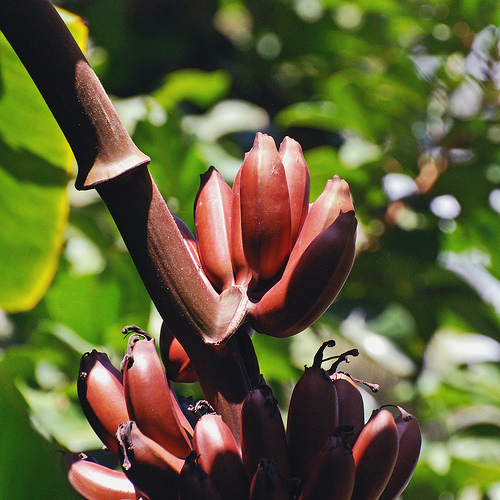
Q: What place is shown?
A: It is a forest.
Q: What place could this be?
A: It is a forest.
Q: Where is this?
A: This is at the forest.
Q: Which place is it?
A: It is a forest.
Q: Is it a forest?
A: Yes, it is a forest.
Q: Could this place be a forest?
A: Yes, it is a forest.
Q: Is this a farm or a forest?
A: It is a forest.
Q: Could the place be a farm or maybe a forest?
A: It is a forest.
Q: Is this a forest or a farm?
A: It is a forest.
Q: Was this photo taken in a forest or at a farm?
A: It was taken at a forest.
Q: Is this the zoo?
A: No, it is the forest.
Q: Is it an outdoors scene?
A: Yes, it is outdoors.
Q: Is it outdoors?
A: Yes, it is outdoors.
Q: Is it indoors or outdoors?
A: It is outdoors.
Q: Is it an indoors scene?
A: No, it is outdoors.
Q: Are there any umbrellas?
A: No, there are no umbrellas.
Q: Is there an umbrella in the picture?
A: No, there are no umbrellas.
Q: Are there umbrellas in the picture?
A: No, there are no umbrellas.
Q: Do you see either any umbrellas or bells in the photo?
A: No, there are no umbrellas or bells.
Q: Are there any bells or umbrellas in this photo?
A: No, there are no umbrellas or bells.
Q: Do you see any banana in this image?
A: Yes, there are bananas.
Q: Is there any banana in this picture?
A: Yes, there are bananas.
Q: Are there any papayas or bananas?
A: Yes, there are bananas.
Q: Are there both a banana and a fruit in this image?
A: Yes, there are both a banana and a fruit.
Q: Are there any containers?
A: No, there are no containers.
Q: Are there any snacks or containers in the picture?
A: No, there are no containers or snacks.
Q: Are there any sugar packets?
A: No, there are no sugar packets.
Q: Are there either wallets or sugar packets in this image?
A: No, there are no sugar packets or wallets.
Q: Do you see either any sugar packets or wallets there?
A: No, there are no sugar packets or wallets.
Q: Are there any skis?
A: No, there are no skis.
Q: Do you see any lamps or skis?
A: No, there are no skis or lamps.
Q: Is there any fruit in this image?
A: Yes, there is a fruit.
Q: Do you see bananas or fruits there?
A: Yes, there is a fruit.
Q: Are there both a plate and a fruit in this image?
A: No, there is a fruit but no plates.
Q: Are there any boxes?
A: No, there are no boxes.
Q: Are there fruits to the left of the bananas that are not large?
A: Yes, there is a fruit to the left of the bananas.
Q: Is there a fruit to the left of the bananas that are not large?
A: Yes, there is a fruit to the left of the bananas.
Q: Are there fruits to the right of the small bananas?
A: No, the fruit is to the left of the bananas.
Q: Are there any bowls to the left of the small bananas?
A: No, there is a fruit to the left of the bananas.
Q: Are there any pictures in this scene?
A: No, there are no pictures.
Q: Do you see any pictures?
A: No, there are no pictures.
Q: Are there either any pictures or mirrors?
A: No, there are no pictures or mirrors.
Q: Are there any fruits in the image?
A: Yes, there is a fruit.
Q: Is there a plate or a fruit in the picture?
A: Yes, there is a fruit.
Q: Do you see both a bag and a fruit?
A: No, there is a fruit but no bags.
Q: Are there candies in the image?
A: No, there are no candies.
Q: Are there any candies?
A: No, there are no candies.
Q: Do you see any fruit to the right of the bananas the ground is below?
A: Yes, there is a fruit to the right of the bananas.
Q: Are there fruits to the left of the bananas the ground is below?
A: No, the fruit is to the right of the bananas.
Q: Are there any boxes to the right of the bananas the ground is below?
A: No, there is a fruit to the right of the bananas.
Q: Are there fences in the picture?
A: No, there are no fences.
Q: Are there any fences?
A: No, there are no fences.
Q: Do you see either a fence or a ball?
A: No, there are no fences or balls.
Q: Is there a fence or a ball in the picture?
A: No, there are no fences or balls.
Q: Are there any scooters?
A: No, there are no scooters.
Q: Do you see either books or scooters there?
A: No, there are no scooters or books.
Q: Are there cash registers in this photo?
A: No, there are no cash registers.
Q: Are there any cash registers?
A: No, there are no cash registers.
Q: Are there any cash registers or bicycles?
A: No, there are no cash registers or bicycles.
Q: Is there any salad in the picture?
A: No, there is no salad.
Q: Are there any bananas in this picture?
A: Yes, there are bananas.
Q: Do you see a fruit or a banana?
A: Yes, there are bananas.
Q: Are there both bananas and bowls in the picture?
A: No, there are bananas but no bowls.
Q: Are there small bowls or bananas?
A: Yes, there are small bananas.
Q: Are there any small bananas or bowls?
A: Yes, there are small bananas.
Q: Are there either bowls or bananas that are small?
A: Yes, the bananas are small.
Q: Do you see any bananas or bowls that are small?
A: Yes, the bananas are small.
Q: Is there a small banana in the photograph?
A: Yes, there are small bananas.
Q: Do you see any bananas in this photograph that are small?
A: Yes, there are bananas that are small.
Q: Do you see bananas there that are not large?
A: Yes, there are small bananas.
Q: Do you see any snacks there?
A: No, there are no snacks.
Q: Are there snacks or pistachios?
A: No, there are no snacks or pistachios.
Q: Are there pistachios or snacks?
A: No, there are no snacks or pistachios.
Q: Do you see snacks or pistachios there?
A: No, there are no snacks or pistachios.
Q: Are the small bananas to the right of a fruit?
A: Yes, the bananas are to the right of a fruit.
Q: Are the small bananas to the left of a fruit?
A: No, the bananas are to the right of a fruit.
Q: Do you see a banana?
A: Yes, there is a banana.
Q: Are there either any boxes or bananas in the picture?
A: Yes, there is a banana.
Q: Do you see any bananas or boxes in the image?
A: Yes, there is a banana.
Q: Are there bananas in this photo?
A: Yes, there is a banana.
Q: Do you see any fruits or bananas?
A: Yes, there is a banana.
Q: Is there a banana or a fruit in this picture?
A: Yes, there is a banana.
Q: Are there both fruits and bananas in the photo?
A: Yes, there are both a banana and a fruit.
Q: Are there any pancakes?
A: No, there are no pancakes.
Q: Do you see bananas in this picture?
A: Yes, there is a banana.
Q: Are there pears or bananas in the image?
A: Yes, there is a banana.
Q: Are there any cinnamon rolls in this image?
A: No, there are no cinnamon rolls.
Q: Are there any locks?
A: No, there are no locks.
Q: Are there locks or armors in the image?
A: No, there are no locks or armors.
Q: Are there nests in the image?
A: No, there are no nests.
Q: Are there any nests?
A: No, there are no nests.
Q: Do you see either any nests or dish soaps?
A: No, there are no nests or dish soaps.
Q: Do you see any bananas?
A: Yes, there is a banana.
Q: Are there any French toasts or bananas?
A: Yes, there is a banana.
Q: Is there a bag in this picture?
A: No, there are no bags.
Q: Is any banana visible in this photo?
A: Yes, there is a banana.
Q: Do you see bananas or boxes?
A: Yes, there is a banana.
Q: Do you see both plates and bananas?
A: No, there is a banana but no plates.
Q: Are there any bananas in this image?
A: Yes, there are bananas.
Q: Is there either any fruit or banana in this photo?
A: Yes, there are bananas.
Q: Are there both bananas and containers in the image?
A: No, there are bananas but no containers.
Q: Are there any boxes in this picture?
A: No, there are no boxes.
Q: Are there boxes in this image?
A: No, there are no boxes.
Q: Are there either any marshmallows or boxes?
A: No, there are no boxes or marshmallows.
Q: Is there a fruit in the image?
A: Yes, there is a fruit.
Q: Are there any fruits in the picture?
A: Yes, there is a fruit.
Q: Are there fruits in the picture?
A: Yes, there is a fruit.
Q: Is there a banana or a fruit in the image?
A: Yes, there is a fruit.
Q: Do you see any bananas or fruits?
A: Yes, there is a fruit.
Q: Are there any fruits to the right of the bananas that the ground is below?
A: Yes, there is a fruit to the right of the bananas.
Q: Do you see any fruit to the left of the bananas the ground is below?
A: No, the fruit is to the right of the bananas.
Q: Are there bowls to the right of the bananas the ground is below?
A: No, there is a fruit to the right of the bananas.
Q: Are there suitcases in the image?
A: No, there are no suitcases.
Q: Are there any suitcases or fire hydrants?
A: No, there are no suitcases or fire hydrants.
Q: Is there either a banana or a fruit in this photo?
A: Yes, there are bananas.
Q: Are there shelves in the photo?
A: No, there are no shelves.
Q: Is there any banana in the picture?
A: Yes, there are bananas.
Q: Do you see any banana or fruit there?
A: Yes, there are bananas.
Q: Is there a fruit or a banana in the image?
A: Yes, there are bananas.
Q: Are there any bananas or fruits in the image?
A: Yes, there are bananas.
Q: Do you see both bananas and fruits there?
A: Yes, there are both bananas and a fruit.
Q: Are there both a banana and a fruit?
A: Yes, there are both a banana and a fruit.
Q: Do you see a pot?
A: No, there are no pots.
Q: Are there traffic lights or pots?
A: No, there are no pots or traffic lights.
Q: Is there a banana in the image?
A: Yes, there is a banana.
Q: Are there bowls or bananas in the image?
A: Yes, there is a banana.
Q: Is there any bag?
A: No, there are no bags.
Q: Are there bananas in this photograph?
A: Yes, there is a banana.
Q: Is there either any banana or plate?
A: Yes, there is a banana.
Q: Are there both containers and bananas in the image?
A: No, there is a banana but no containers.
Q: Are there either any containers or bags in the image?
A: No, there are no containers or bags.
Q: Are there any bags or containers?
A: No, there are no containers or bags.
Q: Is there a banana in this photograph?
A: Yes, there is a banana.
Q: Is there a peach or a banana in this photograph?
A: Yes, there is a banana.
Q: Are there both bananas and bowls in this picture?
A: No, there is a banana but no bowls.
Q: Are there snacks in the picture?
A: No, there are no snacks.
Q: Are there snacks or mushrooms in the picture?
A: No, there are no snacks or mushrooms.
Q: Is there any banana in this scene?
A: Yes, there are bananas.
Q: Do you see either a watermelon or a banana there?
A: Yes, there are bananas.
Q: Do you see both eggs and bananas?
A: No, there are bananas but no eggs.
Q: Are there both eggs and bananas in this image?
A: No, there are bananas but no eggs.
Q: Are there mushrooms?
A: No, there are no mushrooms.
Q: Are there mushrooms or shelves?
A: No, there are no mushrooms or shelves.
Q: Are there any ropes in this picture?
A: No, there are no ropes.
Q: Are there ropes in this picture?
A: No, there are no ropes.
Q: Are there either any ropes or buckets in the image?
A: No, there are no ropes or buckets.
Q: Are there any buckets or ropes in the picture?
A: No, there are no ropes or buckets.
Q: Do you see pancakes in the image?
A: No, there are no pancakes.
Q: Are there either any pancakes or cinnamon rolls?
A: No, there are no pancakes or cinnamon rolls.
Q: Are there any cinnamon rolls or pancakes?
A: No, there are no pancakes or cinnamon rolls.